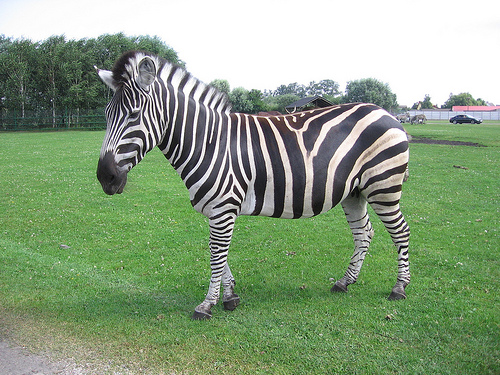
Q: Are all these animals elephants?
A: No, there are both zebras and elephants.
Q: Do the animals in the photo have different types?
A: Yes, they are zebras and elephants.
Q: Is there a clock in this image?
A: No, there are no clocks.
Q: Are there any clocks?
A: No, there are no clocks.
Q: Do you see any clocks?
A: No, there are no clocks.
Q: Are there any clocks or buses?
A: No, there are no clocks or buses.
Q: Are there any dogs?
A: No, there are no dogs.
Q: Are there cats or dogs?
A: No, there are no dogs or cats.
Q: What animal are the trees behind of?
A: The trees are behind the zebra.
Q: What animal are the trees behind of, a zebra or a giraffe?
A: The trees are behind a zebra.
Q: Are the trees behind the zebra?
A: Yes, the trees are behind the zebra.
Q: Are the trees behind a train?
A: No, the trees are behind the zebra.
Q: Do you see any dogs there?
A: No, there are no dogs.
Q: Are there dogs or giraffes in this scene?
A: No, there are no dogs or giraffes.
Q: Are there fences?
A: Yes, there is a fence.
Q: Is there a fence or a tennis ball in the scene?
A: Yes, there is a fence.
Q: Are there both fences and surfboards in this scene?
A: No, there is a fence but no surfboards.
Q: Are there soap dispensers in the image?
A: No, there are no soap dispensers.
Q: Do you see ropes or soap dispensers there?
A: No, there are no soap dispensers or ropes.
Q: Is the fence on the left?
A: Yes, the fence is on the left of the image.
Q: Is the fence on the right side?
A: No, the fence is on the left of the image.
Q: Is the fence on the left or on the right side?
A: The fence is on the left of the image.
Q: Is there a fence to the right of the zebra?
A: No, the fence is to the left of the zebra.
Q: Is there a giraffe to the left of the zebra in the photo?
A: No, there is a fence to the left of the zebra.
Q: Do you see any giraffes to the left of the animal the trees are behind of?
A: No, there is a fence to the left of the zebra.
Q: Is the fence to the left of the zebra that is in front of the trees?
A: Yes, the fence is to the left of the zebra.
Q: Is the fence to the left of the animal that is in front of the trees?
A: Yes, the fence is to the left of the zebra.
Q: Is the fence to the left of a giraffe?
A: No, the fence is to the left of the zebra.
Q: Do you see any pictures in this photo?
A: No, there are no pictures.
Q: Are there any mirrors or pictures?
A: No, there are no pictures or mirrors.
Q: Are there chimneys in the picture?
A: No, there are no chimneys.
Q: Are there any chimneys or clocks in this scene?
A: No, there are no chimneys or clocks.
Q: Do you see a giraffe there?
A: No, there are no giraffes.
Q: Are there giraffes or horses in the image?
A: No, there are no giraffes or horses.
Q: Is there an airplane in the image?
A: No, there are no airplanes.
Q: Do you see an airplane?
A: No, there are no airplanes.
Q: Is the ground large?
A: Yes, the ground is large.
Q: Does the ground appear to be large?
A: Yes, the ground is large.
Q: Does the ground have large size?
A: Yes, the ground is large.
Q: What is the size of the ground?
A: The ground is large.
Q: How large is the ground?
A: The ground is large.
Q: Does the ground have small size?
A: No, the ground is large.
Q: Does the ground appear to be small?
A: No, the ground is large.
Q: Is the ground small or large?
A: The ground is large.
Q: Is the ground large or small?
A: The ground is large.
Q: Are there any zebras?
A: Yes, there is a zebra.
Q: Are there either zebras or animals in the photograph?
A: Yes, there is a zebra.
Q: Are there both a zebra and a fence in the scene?
A: Yes, there are both a zebra and a fence.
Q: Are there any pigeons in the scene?
A: No, there are no pigeons.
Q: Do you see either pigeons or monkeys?
A: No, there are no pigeons or monkeys.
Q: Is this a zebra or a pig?
A: This is a zebra.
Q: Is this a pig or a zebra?
A: This is a zebra.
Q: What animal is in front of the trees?
A: The zebra is in front of the trees.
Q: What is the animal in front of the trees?
A: The animal is a zebra.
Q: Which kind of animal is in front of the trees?
A: The animal is a zebra.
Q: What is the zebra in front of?
A: The zebra is in front of the trees.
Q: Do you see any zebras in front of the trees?
A: Yes, there is a zebra in front of the trees.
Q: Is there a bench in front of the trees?
A: No, there is a zebra in front of the trees.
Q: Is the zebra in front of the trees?
A: Yes, the zebra is in front of the trees.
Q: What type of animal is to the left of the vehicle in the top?
A: The animal is a zebra.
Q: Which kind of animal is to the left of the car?
A: The animal is a zebra.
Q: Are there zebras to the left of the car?
A: Yes, there is a zebra to the left of the car.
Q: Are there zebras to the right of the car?
A: No, the zebra is to the left of the car.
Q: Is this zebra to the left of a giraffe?
A: No, the zebra is to the left of a car.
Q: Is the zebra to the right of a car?
A: No, the zebra is to the left of a car.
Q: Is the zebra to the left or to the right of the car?
A: The zebra is to the left of the car.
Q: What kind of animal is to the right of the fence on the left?
A: The animal is a zebra.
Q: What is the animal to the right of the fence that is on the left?
A: The animal is a zebra.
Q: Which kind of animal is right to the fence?
A: The animal is a zebra.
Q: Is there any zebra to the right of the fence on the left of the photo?
A: Yes, there is a zebra to the right of the fence.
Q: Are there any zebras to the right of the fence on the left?
A: Yes, there is a zebra to the right of the fence.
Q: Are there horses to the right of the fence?
A: No, there is a zebra to the right of the fence.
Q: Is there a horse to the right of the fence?
A: No, there is a zebra to the right of the fence.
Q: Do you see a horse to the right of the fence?
A: No, there is a zebra to the right of the fence.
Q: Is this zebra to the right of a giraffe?
A: No, the zebra is to the right of the fence.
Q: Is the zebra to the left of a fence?
A: No, the zebra is to the right of a fence.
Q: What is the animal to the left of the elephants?
A: The animal is a zebra.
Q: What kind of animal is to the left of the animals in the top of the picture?
A: The animal is a zebra.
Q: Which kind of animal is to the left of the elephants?
A: The animal is a zebra.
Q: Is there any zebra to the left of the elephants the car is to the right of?
A: Yes, there is a zebra to the left of the elephants.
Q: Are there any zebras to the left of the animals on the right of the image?
A: Yes, there is a zebra to the left of the elephants.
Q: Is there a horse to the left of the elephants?
A: No, there is a zebra to the left of the elephants.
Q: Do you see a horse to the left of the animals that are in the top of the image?
A: No, there is a zebra to the left of the elephants.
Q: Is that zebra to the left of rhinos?
A: No, the zebra is to the left of the elephants.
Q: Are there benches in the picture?
A: No, there are no benches.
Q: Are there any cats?
A: No, there are no cats.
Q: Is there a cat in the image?
A: No, there are no cats.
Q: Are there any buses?
A: No, there are no buses.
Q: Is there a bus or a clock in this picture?
A: No, there are no buses or clocks.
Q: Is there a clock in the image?
A: No, there are no clocks.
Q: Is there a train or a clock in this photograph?
A: No, there are no clocks or trains.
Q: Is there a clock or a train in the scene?
A: No, there are no clocks or trains.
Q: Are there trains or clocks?
A: No, there are no clocks or trains.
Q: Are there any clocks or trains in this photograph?
A: No, there are no clocks or trains.